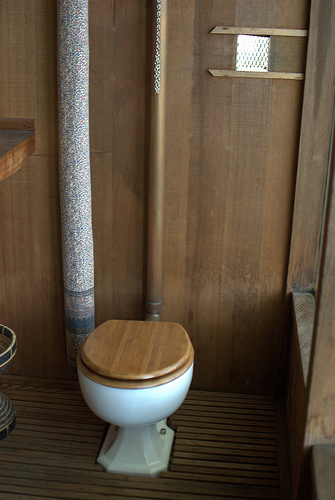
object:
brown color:
[260, 238, 276, 292]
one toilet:
[75, 306, 195, 477]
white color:
[107, 387, 131, 412]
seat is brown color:
[177, 361, 188, 378]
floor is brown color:
[240, 470, 292, 500]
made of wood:
[191, 389, 209, 409]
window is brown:
[277, 7, 335, 434]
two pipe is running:
[51, 1, 171, 319]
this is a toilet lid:
[75, 319, 193, 382]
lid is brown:
[106, 328, 153, 366]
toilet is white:
[105, 395, 165, 426]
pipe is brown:
[144, 10, 171, 297]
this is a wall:
[190, 10, 311, 309]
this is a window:
[284, 0, 331, 466]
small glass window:
[234, 31, 270, 73]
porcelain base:
[95, 421, 180, 474]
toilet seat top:
[77, 305, 191, 381]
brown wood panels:
[84, 371, 183, 391]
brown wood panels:
[189, 456, 227, 473]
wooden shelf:
[0, 110, 43, 191]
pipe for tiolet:
[54, 7, 99, 339]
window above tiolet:
[239, 34, 249, 50]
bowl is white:
[73, 350, 191, 477]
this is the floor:
[8, 377, 48, 422]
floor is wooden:
[1, 467, 80, 497]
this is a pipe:
[143, 0, 175, 316]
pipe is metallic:
[58, 1, 96, 330]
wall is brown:
[89, 9, 129, 52]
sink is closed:
[69, 316, 197, 480]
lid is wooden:
[95, 348, 111, 369]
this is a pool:
[0, 302, 30, 443]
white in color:
[170, 381, 185, 404]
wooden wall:
[207, 82, 292, 111]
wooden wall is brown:
[167, 99, 183, 314]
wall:
[125, 83, 150, 271]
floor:
[209, 400, 256, 435]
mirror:
[235, 33, 269, 72]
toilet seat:
[75, 313, 204, 397]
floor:
[3, 435, 314, 500]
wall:
[4, 4, 58, 337]